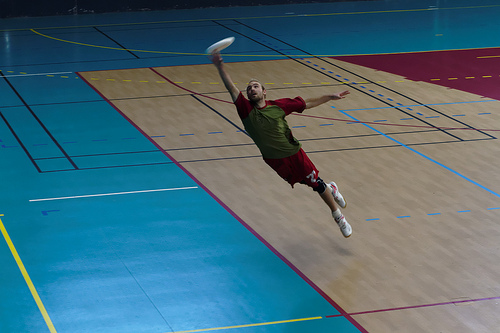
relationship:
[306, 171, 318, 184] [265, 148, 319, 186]
design on shorts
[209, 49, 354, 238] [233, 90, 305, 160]
man in shirt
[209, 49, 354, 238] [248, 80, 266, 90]
man with hair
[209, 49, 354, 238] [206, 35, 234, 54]
man catching frisbee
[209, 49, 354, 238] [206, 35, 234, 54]
man trying to catch frisbee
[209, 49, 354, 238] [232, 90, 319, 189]
man wearing dress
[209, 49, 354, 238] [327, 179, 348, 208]
man wearing shoe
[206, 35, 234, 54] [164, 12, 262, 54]
frisbee in air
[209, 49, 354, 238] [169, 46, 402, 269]
man in mid-air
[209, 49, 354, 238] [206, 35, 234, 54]
man missing frisbee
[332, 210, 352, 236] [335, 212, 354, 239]
shoe of left foot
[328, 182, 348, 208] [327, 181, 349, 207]
shoe of right foot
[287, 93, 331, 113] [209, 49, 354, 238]
left arm of man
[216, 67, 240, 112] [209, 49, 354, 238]
right arm of man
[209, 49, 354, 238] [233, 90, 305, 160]
man wearing shirt